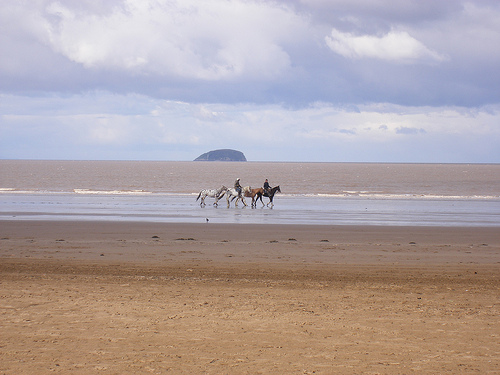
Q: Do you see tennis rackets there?
A: No, there are no tennis rackets.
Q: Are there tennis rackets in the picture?
A: No, there are no tennis rackets.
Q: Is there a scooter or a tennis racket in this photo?
A: No, there are no rackets or scooters.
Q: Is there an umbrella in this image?
A: No, there are no umbrellas.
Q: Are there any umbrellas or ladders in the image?
A: No, there are no umbrellas or ladders.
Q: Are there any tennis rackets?
A: No, there are no tennis rackets.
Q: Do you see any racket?
A: No, there are no rackets.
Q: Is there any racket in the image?
A: No, there are no rackets.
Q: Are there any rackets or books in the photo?
A: No, there are no rackets or books.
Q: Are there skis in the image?
A: No, there are no skis.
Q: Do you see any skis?
A: No, there are no skis.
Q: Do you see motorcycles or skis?
A: No, there are no skis or motorcycles.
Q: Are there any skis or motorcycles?
A: No, there are no skis or motorcycles.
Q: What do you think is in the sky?
A: The clouds are in the sky.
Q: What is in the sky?
A: The clouds are in the sky.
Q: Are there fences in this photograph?
A: No, there are no fences.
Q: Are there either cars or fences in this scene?
A: No, there are no fences or cars.